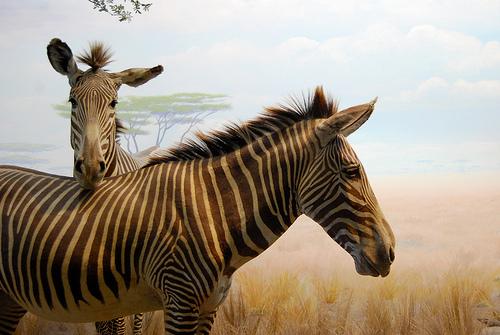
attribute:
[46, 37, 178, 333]
zebra — staring 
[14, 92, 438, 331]
zebra — large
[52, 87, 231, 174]
tree — tall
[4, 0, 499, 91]
sky — cloudy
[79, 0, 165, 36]
leaves — small, green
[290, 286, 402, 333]
grass — tall, brown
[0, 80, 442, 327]
zebra — largest, black, white, taller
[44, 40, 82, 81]
ear — black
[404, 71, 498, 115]
cloud — white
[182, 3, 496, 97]
cloud — white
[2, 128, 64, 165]
cloud — white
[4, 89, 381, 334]
zebra — large, brown, looking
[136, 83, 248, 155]
tree — distant, tall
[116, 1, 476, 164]
clouds — white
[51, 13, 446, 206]
sky — blue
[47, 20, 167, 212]
zebra — vertical, standing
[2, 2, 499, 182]
sky — blue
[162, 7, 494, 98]
clouds — light blue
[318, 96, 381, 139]
ears — pointing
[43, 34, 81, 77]
ear — high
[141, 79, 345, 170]
mane — black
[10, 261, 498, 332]
wheat — brown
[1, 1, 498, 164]
sky — cloudy